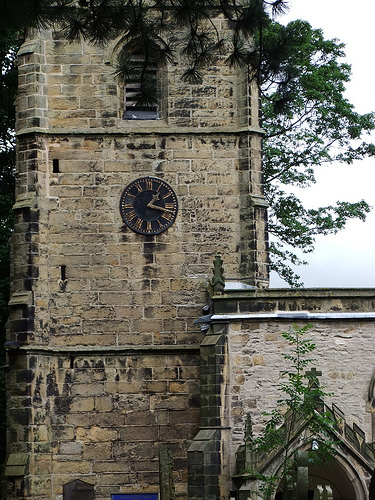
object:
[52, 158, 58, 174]
opening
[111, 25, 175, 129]
building window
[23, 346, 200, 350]
ledge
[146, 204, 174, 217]
gold hands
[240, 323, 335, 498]
plant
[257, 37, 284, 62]
branches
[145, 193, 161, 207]
hour hand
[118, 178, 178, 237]
clock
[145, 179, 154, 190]
numeral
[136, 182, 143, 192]
numeral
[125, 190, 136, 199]
numeral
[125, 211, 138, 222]
numeral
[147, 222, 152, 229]
numeral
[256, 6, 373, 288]
trees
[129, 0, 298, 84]
tree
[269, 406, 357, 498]
door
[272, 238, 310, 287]
branch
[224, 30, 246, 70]
leaves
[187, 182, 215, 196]
bricks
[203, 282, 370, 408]
building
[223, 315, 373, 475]
wall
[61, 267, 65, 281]
hole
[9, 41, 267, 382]
tower wall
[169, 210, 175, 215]
minute hand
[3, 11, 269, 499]
building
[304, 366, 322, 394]
cross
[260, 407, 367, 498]
doorway